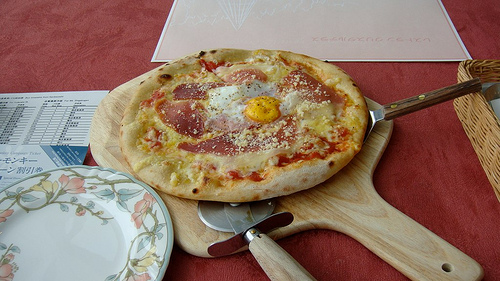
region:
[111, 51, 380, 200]
a pizza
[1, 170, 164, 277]
a white plate with flowery edges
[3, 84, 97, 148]
a printed sheet of paper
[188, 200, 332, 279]
a metal pizza cutter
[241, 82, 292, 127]
a egg yolk on a pizza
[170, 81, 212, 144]
slices of ham on a pizza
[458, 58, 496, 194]
a wicker basket on a table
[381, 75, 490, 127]
a wooden handle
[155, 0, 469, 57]
a framed poster on a table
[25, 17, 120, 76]
red tablecloth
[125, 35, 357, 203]
A pizza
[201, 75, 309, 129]
an egg on a pizza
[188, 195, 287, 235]
A pizza cutter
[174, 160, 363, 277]
the pizza on the pizza cutter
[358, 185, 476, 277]
The handle of the tray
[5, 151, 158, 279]
A plate on the table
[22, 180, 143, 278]
Flowers on the plate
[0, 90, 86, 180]
Paper on the table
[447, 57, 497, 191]
A wicker basket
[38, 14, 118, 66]
Red velvet on the table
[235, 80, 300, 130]
a cooked egg yolk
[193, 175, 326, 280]
a wood handled pizza cutter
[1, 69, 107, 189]
a piece of paper work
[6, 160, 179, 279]
a plate with floral design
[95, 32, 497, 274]
a wood pizza board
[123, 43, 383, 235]
a whole round pizza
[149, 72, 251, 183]
some thin slices of meat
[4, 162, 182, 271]
a plate with a blue rim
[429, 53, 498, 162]
a wicker basket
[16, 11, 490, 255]
a red table cloth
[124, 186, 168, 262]
A floral pattern on the plate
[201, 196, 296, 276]
A pizza cutter under the pizza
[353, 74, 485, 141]
A spatula wedged under the pizza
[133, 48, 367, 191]
A pizza with Parmesan cheese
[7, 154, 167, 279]
An empty plate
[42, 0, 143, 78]
A red table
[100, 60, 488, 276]
A wooden serving tool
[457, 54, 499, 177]
The basket is made of wood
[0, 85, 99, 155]
A menu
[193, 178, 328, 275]
pizza cutter on pizza board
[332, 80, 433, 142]
pizza server on the pizza board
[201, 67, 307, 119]
egg on top of pizza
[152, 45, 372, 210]
pizza is out of the oven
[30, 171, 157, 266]
plate next to pizza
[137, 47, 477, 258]
pizza on pizza board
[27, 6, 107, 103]
table cloth is red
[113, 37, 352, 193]
pizza is uncut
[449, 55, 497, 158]
basket on the side of board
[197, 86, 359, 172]
melted cheese on top of pizza